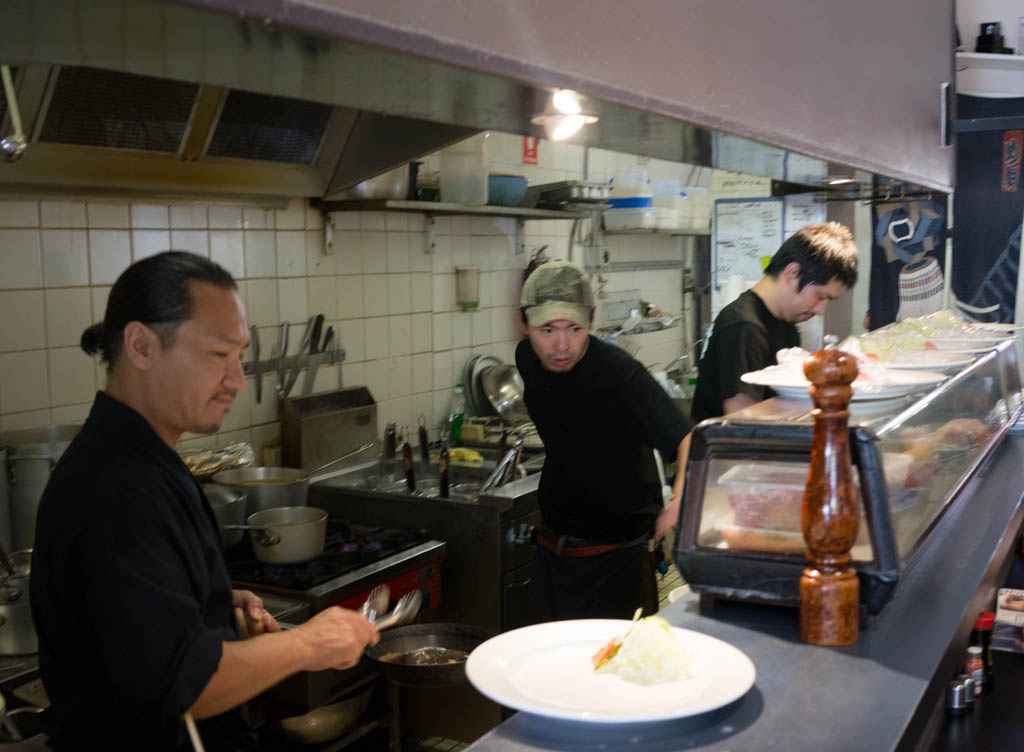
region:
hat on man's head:
[521, 256, 607, 334]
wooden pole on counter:
[801, 350, 878, 660]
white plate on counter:
[445, 620, 782, 748]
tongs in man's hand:
[354, 578, 427, 656]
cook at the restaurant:
[18, 234, 436, 748]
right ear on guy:
[773, 259, 802, 302]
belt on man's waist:
[530, 521, 660, 566]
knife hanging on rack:
[293, 304, 325, 402]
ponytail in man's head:
[59, 312, 121, 358]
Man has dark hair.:
[51, 278, 302, 355]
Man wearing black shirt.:
[57, 451, 223, 718]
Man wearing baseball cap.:
[508, 262, 610, 340]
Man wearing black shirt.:
[531, 361, 675, 526]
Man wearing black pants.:
[531, 533, 672, 622]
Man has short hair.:
[740, 220, 874, 300]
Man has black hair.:
[762, 225, 896, 306]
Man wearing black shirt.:
[707, 284, 777, 387]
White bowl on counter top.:
[445, 600, 730, 741]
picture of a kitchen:
[21, 49, 1009, 738]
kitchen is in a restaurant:
[45, 47, 1020, 737]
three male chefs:
[17, 75, 909, 689]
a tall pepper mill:
[811, 333, 866, 627]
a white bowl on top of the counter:
[491, 594, 749, 749]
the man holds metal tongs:
[353, 583, 424, 640]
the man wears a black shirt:
[84, 450, 244, 741]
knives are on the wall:
[244, 303, 377, 379]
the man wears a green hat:
[529, 270, 578, 321]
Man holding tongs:
[354, 564, 431, 644]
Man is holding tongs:
[351, 555, 438, 639]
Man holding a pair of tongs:
[348, 579, 424, 634]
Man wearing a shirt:
[506, 327, 700, 543]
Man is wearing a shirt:
[506, 317, 694, 568]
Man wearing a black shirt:
[512, 310, 696, 560]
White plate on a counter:
[459, 611, 764, 728]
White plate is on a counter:
[457, 596, 777, 736]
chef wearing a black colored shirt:
[27, 245, 381, 733]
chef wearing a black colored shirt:
[520, 250, 691, 623]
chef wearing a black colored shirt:
[703, 216, 849, 407]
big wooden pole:
[792, 329, 875, 655]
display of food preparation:
[631, 305, 1020, 609]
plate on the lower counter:
[443, 609, 770, 739]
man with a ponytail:
[28, 241, 392, 750]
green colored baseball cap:
[502, 247, 607, 347]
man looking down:
[688, 218, 867, 504]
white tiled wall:
[9, 200, 585, 520]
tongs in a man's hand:
[345, 575, 435, 651]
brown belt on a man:
[522, 519, 652, 571]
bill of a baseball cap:
[522, 297, 603, 332]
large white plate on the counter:
[457, 610, 758, 725]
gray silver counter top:
[456, 402, 1017, 745]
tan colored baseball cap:
[509, 256, 593, 330]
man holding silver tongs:
[23, 242, 419, 727]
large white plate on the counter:
[743, 355, 949, 406]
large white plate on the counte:
[841, 333, 982, 372]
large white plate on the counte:
[910, 311, 1015, 347]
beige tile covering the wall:
[0, 185, 590, 464]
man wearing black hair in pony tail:
[26, 252, 428, 743]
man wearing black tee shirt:
[686, 219, 860, 431]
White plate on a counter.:
[439, 614, 759, 738]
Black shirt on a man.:
[21, 405, 262, 716]